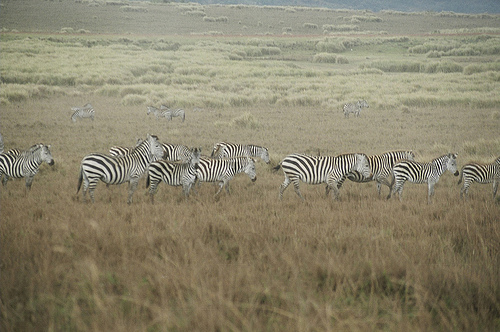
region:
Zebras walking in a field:
[0, 143, 499, 208]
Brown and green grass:
[5, 228, 499, 329]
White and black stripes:
[86, 152, 124, 187]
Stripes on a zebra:
[281, 153, 361, 185]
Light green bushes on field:
[0, 37, 499, 114]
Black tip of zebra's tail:
[76, 173, 86, 197]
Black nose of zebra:
[453, 165, 457, 178]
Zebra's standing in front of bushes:
[67, 102, 389, 121]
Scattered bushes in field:
[0, 0, 499, 42]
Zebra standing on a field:
[340, 101, 364, 117]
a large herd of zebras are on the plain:
[3, 85, 496, 220]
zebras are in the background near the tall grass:
[58, 90, 378, 132]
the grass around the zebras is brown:
[1, 107, 498, 319]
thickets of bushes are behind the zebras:
[5, 27, 498, 117]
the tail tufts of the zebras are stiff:
[68, 159, 283, 196]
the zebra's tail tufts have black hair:
[70, 160, 294, 197]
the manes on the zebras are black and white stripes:
[333, 148, 447, 167]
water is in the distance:
[198, 2, 498, 22]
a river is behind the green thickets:
[173, 0, 498, 85]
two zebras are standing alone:
[133, 98, 195, 130]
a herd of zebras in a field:
[0, 128, 497, 204]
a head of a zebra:
[38, 138, 57, 169]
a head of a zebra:
[146, 129, 172, 162]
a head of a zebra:
[351, 146, 378, 183]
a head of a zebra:
[446, 148, 461, 178]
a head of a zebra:
[184, 143, 210, 172]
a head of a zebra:
[256, 145, 275, 167]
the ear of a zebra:
[145, 130, 157, 142]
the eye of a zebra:
[153, 140, 164, 152]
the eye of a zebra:
[362, 159, 371, 173]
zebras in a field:
[53, 58, 488, 282]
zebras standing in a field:
[11, 14, 401, 299]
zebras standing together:
[87, 83, 406, 269]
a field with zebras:
[60, 15, 483, 312]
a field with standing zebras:
[91, 68, 441, 321]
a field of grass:
[97, 11, 457, 329]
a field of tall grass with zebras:
[64, 33, 399, 321]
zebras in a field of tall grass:
[114, 31, 395, 307]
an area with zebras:
[57, 44, 452, 330]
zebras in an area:
[47, 69, 289, 301]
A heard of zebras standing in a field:
[1, 79, 491, 234]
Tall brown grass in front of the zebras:
[64, 235, 496, 330]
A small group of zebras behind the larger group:
[61, 92, 383, 129]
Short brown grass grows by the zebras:
[36, 194, 440, 219]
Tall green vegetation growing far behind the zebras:
[14, 37, 496, 109]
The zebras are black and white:
[1, 132, 494, 207]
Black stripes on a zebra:
[286, 155, 325, 178]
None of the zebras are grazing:
[0, 123, 491, 210]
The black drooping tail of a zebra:
[71, 164, 86, 194]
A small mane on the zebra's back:
[124, 129, 152, 154]